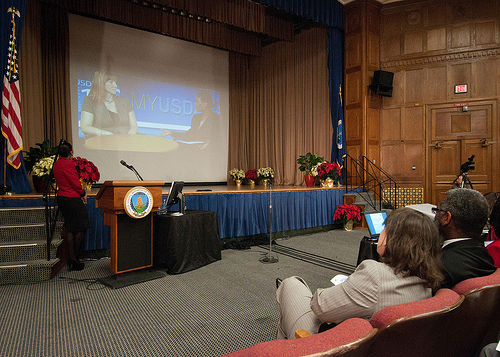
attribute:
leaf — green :
[294, 152, 311, 166]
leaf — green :
[300, 158, 315, 168]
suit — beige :
[269, 257, 433, 341]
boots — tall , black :
[52, 240, 91, 272]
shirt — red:
[49, 153, 89, 201]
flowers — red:
[72, 156, 102, 183]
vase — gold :
[79, 174, 93, 199]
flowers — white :
[227, 166, 250, 179]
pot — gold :
[232, 174, 245, 191]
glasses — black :
[428, 200, 453, 216]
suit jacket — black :
[431, 238, 498, 283]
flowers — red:
[328, 200, 368, 226]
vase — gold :
[339, 216, 362, 234]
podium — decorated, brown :
[89, 174, 168, 286]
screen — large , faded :
[64, 19, 239, 185]